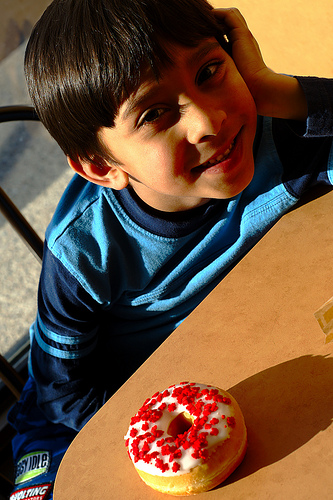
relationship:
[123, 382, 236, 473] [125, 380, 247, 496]
sprinkles on top of doughnut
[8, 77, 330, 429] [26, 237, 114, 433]
shirt has sleeve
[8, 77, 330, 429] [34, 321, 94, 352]
shirt has stripe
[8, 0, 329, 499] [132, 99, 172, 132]
boy has eye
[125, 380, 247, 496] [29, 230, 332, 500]
doughnut on table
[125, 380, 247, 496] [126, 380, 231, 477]
doughnut with cream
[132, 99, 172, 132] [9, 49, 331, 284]
eye of boy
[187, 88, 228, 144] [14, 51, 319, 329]
nose of boy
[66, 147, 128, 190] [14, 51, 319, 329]
ear of boy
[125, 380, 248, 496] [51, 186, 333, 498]
doughnut on table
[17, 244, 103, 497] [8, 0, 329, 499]
hand of boy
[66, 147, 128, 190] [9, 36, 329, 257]
ear of boy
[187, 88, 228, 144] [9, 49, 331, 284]
nose of boy